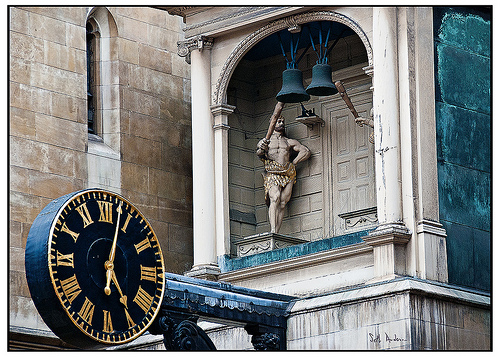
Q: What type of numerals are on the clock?
A: Roman.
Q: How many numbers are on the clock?
A: 12.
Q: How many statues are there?
A: 1.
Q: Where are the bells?
A: Hanging from the building.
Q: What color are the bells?
A: Blue.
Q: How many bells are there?
A: 2.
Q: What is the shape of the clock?
A: Circle.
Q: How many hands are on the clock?
A: 2.